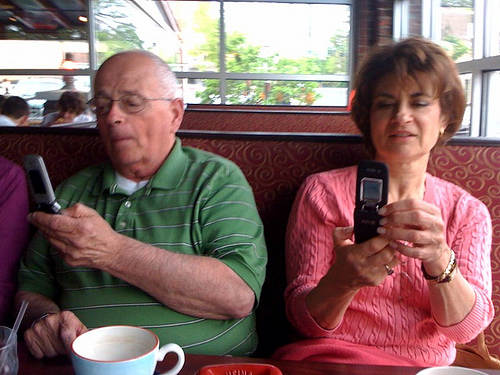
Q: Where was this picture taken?
A: Restaurant.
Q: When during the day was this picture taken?
A: Daytime.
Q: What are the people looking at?
A: Cell phones.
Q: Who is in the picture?
A: Man and woman.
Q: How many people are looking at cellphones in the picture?
A: Two.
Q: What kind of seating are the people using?
A: Booth.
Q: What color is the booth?
A: Red.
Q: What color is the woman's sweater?
A: Pink.